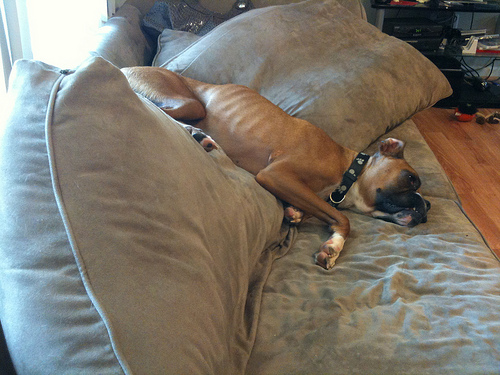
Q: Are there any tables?
A: Yes, there is a table.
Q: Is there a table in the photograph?
A: Yes, there is a table.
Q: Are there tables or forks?
A: Yes, there is a table.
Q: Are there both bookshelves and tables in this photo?
A: No, there is a table but no bookshelves.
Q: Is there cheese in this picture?
A: No, there is no cheese.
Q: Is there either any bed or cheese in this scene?
A: No, there are no cheese or beds.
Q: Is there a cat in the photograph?
A: No, there are no cats.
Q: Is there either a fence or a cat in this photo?
A: No, there are no cats or fences.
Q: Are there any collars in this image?
A: Yes, there is a collar.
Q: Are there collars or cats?
A: Yes, there is a collar.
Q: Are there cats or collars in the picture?
A: Yes, there is a collar.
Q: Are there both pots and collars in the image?
A: No, there is a collar but no pots.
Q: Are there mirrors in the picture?
A: No, there are no mirrors.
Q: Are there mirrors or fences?
A: No, there are no mirrors or fences.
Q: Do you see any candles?
A: No, there are no candles.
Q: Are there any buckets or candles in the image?
A: No, there are no candles or buckets.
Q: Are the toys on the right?
A: Yes, the toys are on the right of the image.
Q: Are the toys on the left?
A: No, the toys are on the right of the image.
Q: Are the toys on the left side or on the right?
A: The toys are on the right of the image.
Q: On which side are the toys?
A: The toys are on the right of the image.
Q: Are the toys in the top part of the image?
A: Yes, the toys are in the top of the image.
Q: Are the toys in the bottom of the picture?
A: No, the toys are in the top of the image.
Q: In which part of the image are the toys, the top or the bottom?
A: The toys are in the top of the image.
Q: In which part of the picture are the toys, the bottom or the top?
A: The toys are in the top of the image.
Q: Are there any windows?
A: Yes, there is a window.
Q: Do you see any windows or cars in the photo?
A: Yes, there is a window.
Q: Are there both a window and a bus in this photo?
A: No, there is a window but no buses.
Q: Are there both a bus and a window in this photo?
A: No, there is a window but no buses.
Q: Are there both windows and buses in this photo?
A: No, there is a window but no buses.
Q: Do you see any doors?
A: No, there are no doors.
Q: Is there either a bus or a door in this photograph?
A: No, there are no doors or buses.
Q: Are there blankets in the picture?
A: No, there are no blankets.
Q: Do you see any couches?
A: Yes, there is a couch.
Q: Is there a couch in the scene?
A: Yes, there is a couch.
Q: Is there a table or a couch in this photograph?
A: Yes, there is a couch.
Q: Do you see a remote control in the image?
A: No, there are no remote controls.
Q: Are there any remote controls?
A: No, there are no remote controls.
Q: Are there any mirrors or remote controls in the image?
A: No, there are no remote controls or mirrors.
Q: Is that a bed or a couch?
A: That is a couch.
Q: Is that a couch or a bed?
A: That is a couch.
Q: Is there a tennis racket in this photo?
A: No, there are no rackets.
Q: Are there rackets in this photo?
A: No, there are no rackets.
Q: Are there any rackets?
A: No, there are no rackets.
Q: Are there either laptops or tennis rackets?
A: No, there are no tennis rackets or laptops.